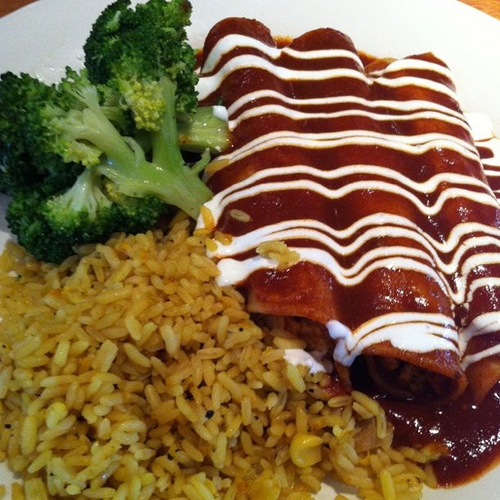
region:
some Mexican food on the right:
[145, 1, 499, 465]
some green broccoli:
[2, 0, 287, 285]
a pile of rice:
[0, 192, 481, 490]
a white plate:
[6, 0, 498, 492]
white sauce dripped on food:
[173, 16, 498, 407]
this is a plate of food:
[13, 15, 491, 499]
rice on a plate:
[0, 197, 388, 497]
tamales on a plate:
[168, 9, 497, 411]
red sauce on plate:
[181, 6, 498, 485]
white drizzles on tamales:
[191, 15, 494, 422]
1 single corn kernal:
[256, 413, 362, 480]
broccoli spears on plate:
[6, 5, 229, 283]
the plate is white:
[2, 5, 497, 145]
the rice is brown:
[28, 253, 295, 496]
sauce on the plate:
[368, 382, 498, 492]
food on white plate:
[1, 1, 498, 496]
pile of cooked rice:
[2, 228, 434, 495]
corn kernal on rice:
[291, 433, 321, 468]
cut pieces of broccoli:
[5, 3, 225, 253]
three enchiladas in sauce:
[198, 15, 498, 407]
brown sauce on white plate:
[378, 404, 498, 499]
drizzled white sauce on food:
[202, 42, 494, 351]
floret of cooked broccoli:
[90, 4, 194, 124]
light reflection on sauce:
[390, 408, 499, 457]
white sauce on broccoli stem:
[211, 104, 236, 130]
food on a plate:
[3, 75, 480, 382]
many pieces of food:
[86, 269, 233, 408]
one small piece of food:
[154, 313, 185, 359]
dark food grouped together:
[21, 227, 248, 467]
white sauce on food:
[343, 214, 455, 292]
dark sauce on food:
[406, 388, 485, 453]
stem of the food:
[140, 140, 227, 232]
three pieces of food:
[202, 35, 474, 305]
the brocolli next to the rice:
[3, 5, 223, 232]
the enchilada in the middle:
[291, 29, 463, 396]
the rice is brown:
[8, 247, 375, 485]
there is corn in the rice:
[287, 434, 324, 467]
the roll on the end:
[214, 30, 336, 365]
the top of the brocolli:
[105, 5, 201, 92]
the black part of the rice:
[200, 406, 222, 419]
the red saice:
[371, 364, 480, 471]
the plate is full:
[15, 28, 493, 471]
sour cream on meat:
[196, 24, 490, 425]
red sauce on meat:
[191, 43, 456, 358]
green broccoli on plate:
[1, 28, 196, 230]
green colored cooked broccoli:
[1, 2, 228, 262]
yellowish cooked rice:
[4, 204, 448, 498]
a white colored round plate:
[1, 2, 496, 260]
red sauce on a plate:
[353, 380, 499, 487]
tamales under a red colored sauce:
[183, 15, 494, 405]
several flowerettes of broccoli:
[1, 0, 228, 225]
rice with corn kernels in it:
[1, 239, 388, 491]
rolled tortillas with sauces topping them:
[207, 15, 498, 390]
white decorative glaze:
[224, 90, 499, 287]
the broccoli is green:
[1, 3, 209, 215]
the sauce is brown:
[210, 18, 499, 335]